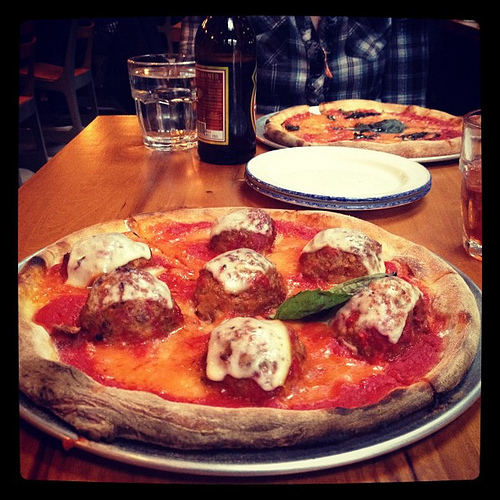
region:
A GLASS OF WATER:
[119, 48, 212, 157]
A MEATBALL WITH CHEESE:
[192, 316, 319, 396]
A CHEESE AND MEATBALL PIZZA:
[20, 198, 482, 463]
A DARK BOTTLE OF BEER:
[181, 15, 266, 175]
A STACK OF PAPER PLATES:
[238, 141, 435, 215]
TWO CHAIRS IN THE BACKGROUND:
[22, 17, 102, 165]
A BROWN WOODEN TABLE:
[24, 161, 495, 489]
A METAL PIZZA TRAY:
[22, 374, 476, 481]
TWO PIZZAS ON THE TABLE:
[20, 68, 494, 464]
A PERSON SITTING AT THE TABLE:
[198, 14, 446, 126]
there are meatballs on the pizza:
[14, 207, 479, 473]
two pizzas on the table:
[3, 99, 484, 481]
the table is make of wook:
[17, 114, 478, 478]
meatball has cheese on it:
[202, 317, 306, 396]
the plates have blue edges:
[243, 147, 432, 212]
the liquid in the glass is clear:
[128, 53, 201, 153]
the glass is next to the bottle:
[128, 15, 255, 164]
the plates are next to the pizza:
[20, 148, 485, 473]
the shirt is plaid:
[170, 18, 428, 115]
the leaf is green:
[273, 272, 394, 324]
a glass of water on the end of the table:
[120, 51, 227, 158]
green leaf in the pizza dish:
[276, 271, 398, 326]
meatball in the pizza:
[200, 311, 315, 398]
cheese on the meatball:
[206, 310, 296, 398]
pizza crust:
[63, 372, 271, 475]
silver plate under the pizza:
[28, 413, 448, 475]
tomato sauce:
[349, 323, 436, 400]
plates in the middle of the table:
[257, 137, 432, 229]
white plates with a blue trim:
[257, 135, 454, 217]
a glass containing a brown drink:
[446, 107, 498, 263]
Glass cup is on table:
[125, 44, 206, 166]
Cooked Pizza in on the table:
[11, 190, 488, 461]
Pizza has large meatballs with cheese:
[60, 208, 430, 410]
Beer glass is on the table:
[193, 17, 280, 179]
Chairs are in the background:
[7, 25, 119, 146]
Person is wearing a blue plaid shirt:
[220, 0, 442, 97]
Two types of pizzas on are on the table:
[40, 100, 478, 428]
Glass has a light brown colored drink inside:
[440, 100, 499, 271]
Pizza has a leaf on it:
[251, 274, 387, 339]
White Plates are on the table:
[246, 128, 438, 228]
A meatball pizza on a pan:
[11, 201, 481, 466]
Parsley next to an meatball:
[260, 245, 435, 331]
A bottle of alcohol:
[185, 6, 271, 159]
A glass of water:
[125, 42, 197, 148]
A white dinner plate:
[241, 135, 442, 205]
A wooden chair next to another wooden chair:
[35, 10, 100, 145]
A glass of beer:
[445, 96, 496, 251]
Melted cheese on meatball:
[62, 222, 147, 277]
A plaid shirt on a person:
[253, 0, 418, 101]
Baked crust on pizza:
[103, 386, 263, 448]